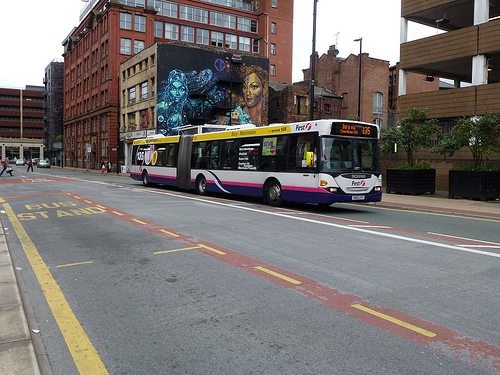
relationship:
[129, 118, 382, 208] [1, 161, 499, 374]
bus on highway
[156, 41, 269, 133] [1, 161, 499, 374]
posters are beside highway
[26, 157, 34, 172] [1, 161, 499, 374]
person crossing highway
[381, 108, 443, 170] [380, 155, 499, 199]
plant on wall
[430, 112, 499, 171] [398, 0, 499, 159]
tree by parking ramp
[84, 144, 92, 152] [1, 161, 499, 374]
sign next to highway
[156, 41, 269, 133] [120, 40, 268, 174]
mural on building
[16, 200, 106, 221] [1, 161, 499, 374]
words are on highway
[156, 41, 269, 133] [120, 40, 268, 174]
posters on side of building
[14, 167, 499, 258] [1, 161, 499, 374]
line on road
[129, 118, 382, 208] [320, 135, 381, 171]
bus has a windshield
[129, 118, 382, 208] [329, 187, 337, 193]
bus has a light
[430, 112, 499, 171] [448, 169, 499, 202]
tree in planter